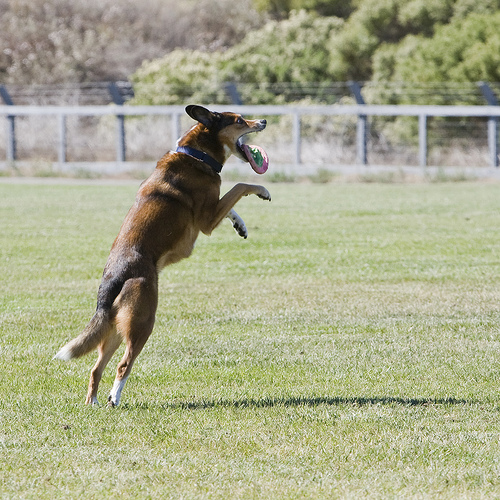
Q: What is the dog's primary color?
A: Brown.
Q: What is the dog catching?
A: Toy.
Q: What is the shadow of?
A: Dog.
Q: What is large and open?
A: Field.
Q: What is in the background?
A: Fence.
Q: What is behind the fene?
A: Trees.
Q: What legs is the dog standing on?
A: Hind legs.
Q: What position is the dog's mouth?
A: Open.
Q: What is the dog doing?
A: Dog jumping in air to catch toy.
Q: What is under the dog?
A: Shadow of dog being cast in grass.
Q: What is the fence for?
A: To enclose the park.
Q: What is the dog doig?
A: Brown dog catching toy.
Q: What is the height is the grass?
A: Short brown and green grass.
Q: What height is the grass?
A: Short.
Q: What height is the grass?
A: Short.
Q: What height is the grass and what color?
A: Short brown and green grass.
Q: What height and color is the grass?
A: Short brown and green grass.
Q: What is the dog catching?
A: A toy.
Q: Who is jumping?
A: A dog.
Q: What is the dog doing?
A: Jumping.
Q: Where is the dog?
A: In a park.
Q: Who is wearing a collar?
A: A dog.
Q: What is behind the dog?
A: A fence.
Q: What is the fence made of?
A: Wire.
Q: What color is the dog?
A: Brown and black.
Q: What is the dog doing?
A: Playing.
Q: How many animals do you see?
A: One.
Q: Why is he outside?
A: To play frisbee.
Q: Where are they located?
A: Outside in the grass.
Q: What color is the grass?
A: Green.